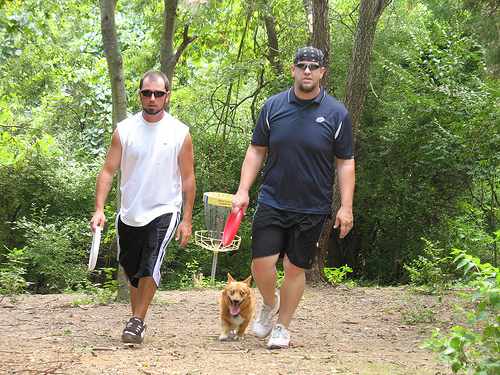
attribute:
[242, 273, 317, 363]
sneakers — white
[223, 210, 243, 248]
frisbee — red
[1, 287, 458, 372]
gravel — brown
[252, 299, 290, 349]
shoe — red and white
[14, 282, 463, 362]
path — dirt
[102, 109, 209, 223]
shirt — white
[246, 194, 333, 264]
shorts — black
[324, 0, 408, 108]
trees — large, green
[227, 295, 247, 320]
mouth — dog's, open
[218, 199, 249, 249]
disc — red, plastic, flying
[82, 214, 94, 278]
frisbee — white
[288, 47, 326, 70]
bandanna — black, white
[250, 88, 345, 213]
shirt — polo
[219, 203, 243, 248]
frisbee — golf target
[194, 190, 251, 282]
stand — yellow frisbee, golf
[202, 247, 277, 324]
dog — brown and white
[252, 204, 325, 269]
shorts — black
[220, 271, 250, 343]
dog — small, brown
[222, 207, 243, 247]
frisbee — round, red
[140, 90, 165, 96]
sunglasses — black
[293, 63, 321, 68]
sunglasses — black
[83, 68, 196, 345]
guys — black and white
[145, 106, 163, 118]
beard — man's, black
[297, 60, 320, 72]
sunglasses — dark, black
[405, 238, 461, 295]
leaves — green, tree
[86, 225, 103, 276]
frisbee — white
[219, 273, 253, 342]
dog — small , short, brown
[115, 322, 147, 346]
shoe — black and white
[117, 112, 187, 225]
t-shirt — white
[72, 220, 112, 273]
frisbee — white, round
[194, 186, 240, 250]
frisbee net — yellow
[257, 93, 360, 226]
shirt — dark blue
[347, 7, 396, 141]
branch — part of, tree, long